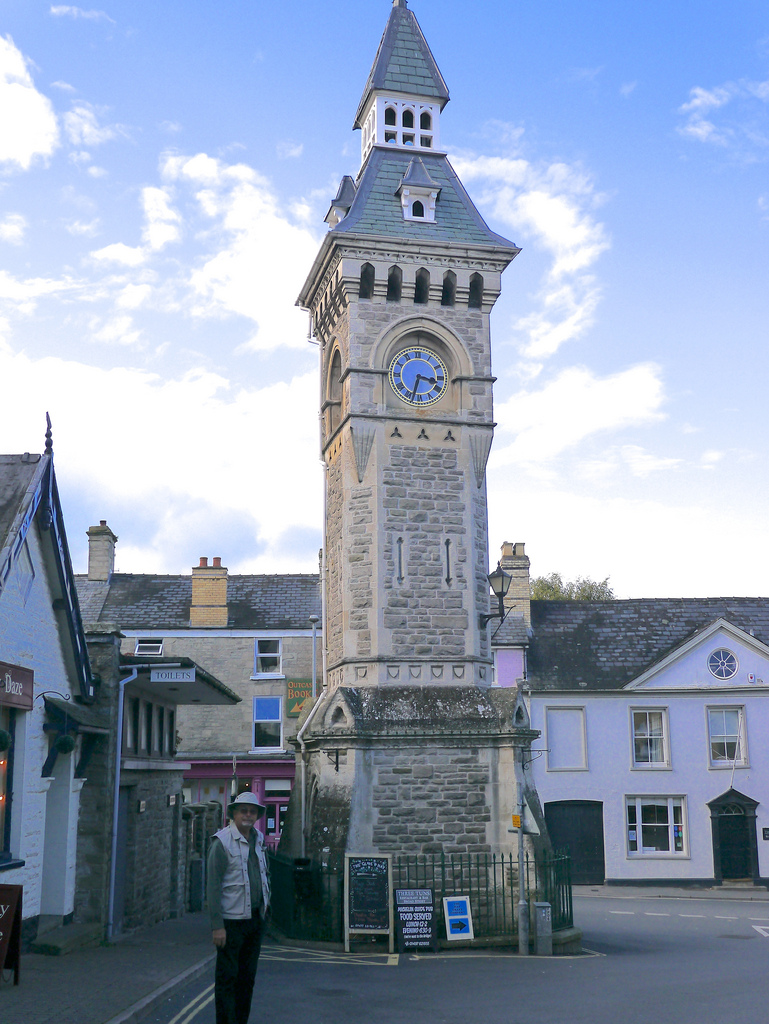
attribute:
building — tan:
[80, 519, 454, 918]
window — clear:
[132, 639, 164, 659]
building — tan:
[79, 566, 422, 931]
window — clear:
[263, 798, 276, 836]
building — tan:
[79, 564, 458, 945]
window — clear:
[261, 776, 290, 792]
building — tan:
[85, 631, 239, 951]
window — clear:
[123, 696, 142, 750]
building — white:
[3, 412, 82, 975]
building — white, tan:
[63, 523, 767, 899]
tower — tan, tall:
[294, 1, 576, 967]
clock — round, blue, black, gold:
[392, 342, 445, 401]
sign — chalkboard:
[341, 851, 393, 943]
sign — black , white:
[394, 884, 436, 949]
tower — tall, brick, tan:
[275, 3, 524, 912]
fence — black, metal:
[259, 849, 581, 950]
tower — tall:
[237, 0, 579, 942]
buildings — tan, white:
[68, 534, 767, 903]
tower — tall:
[263, 0, 559, 946]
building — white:
[526, 602, 765, 894]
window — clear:
[628, 702, 674, 769]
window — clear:
[701, 699, 751, 768]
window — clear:
[622, 793, 684, 852]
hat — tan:
[227, 787, 265, 812]